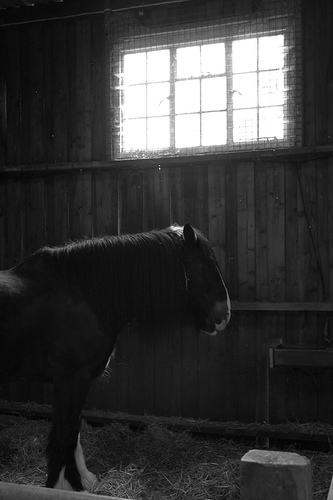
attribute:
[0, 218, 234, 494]
horse — dark, on the horse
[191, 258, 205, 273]
eye — on the horse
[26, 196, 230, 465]
horse — with leg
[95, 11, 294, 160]
window — next to horse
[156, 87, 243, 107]
handles — next to horse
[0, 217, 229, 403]
horse — dark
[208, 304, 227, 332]
nose — white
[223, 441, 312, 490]
stone — next to horse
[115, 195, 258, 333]
head — of a horse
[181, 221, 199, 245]
ear — on the horse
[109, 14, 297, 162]
window — next to the horse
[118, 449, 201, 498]
grass — dry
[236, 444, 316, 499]
stone — next to horse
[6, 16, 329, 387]
photo — white, black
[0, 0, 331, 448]
wall — next to horse, wooden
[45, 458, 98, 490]
feet — white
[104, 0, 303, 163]
window — screened